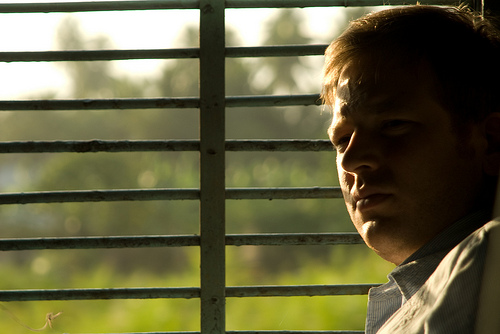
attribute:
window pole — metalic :
[226, 278, 366, 302]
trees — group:
[37, 24, 313, 243]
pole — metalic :
[1, 40, 205, 72]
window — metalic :
[3, 5, 351, 332]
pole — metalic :
[74, 181, 139, 223]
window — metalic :
[0, 2, 457, 331]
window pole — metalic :
[1, 47, 203, 64]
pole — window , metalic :
[8, 281, 191, 310]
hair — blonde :
[324, 5, 497, 105]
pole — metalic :
[3, 278, 199, 301]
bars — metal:
[2, 41, 339, 65]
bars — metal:
[0, 85, 323, 115]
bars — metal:
[0, 135, 347, 157]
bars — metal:
[2, 178, 351, 206]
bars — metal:
[0, 227, 370, 247]